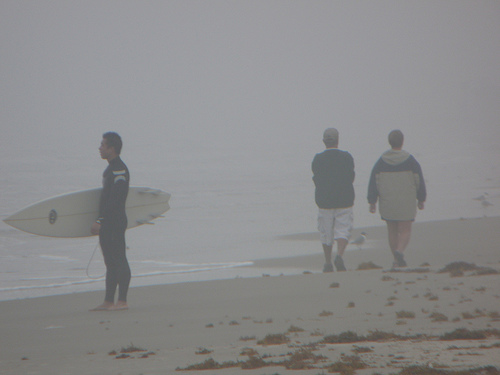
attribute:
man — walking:
[302, 120, 358, 267]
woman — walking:
[366, 114, 433, 281]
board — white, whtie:
[19, 192, 106, 243]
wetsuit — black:
[96, 162, 134, 298]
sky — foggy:
[121, 27, 155, 51]